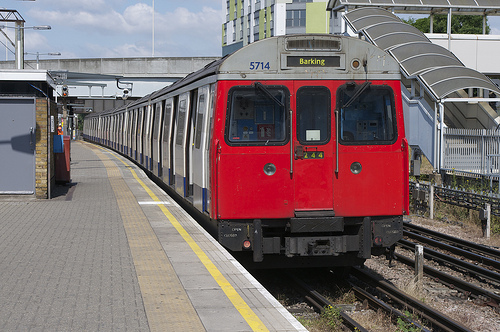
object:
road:
[0, 139, 309, 332]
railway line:
[291, 280, 366, 332]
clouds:
[0, 0, 223, 61]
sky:
[0, 0, 500, 61]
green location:
[298, 57, 325, 65]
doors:
[336, 80, 402, 214]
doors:
[218, 79, 293, 217]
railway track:
[389, 250, 500, 307]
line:
[77, 139, 271, 331]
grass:
[397, 316, 423, 331]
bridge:
[0, 56, 223, 78]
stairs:
[442, 162, 498, 167]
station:
[0, 0, 500, 332]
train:
[82, 32, 409, 265]